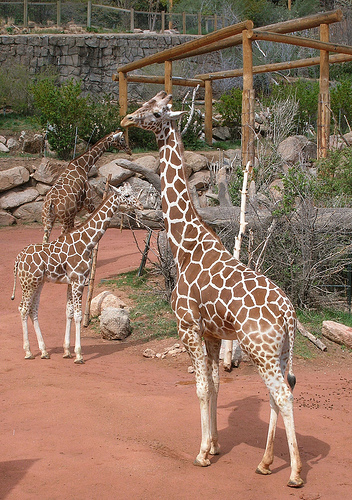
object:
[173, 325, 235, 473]
legs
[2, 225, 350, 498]
floor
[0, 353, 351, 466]
dirt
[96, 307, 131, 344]
stones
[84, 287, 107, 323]
stones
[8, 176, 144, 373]
baby giraffe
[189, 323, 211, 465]
front leg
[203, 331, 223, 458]
front leg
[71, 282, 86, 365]
front leg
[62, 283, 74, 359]
front leg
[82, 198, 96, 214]
front leg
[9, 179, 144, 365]
giraffe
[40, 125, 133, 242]
giraffe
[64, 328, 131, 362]
shadow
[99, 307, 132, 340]
rock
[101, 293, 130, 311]
rock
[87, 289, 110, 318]
rock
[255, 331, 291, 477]
back leg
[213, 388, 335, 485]
shadow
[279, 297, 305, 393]
tail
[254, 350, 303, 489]
legs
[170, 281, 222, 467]
front legs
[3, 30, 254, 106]
wall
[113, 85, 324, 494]
mom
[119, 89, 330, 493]
giraffe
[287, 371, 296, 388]
turf